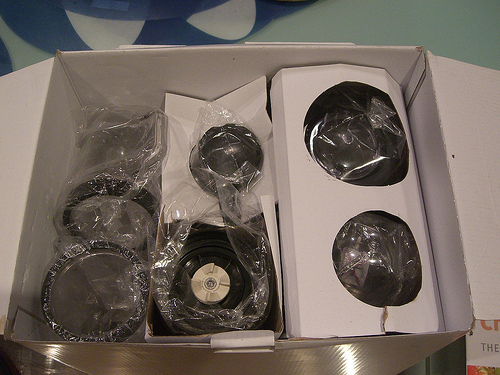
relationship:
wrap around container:
[68, 105, 165, 246] [64, 182, 162, 251]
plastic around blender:
[158, 186, 272, 337] [166, 240, 269, 318]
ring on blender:
[170, 241, 252, 313] [166, 240, 269, 318]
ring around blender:
[170, 241, 252, 313] [166, 240, 269, 318]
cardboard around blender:
[163, 74, 277, 226] [166, 240, 269, 318]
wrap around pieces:
[68, 105, 165, 246] [43, 125, 272, 341]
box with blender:
[1, 44, 499, 372] [166, 240, 269, 318]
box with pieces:
[1, 44, 499, 372] [43, 125, 272, 341]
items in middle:
[185, 115, 272, 203] [164, 46, 291, 343]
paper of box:
[262, 196, 284, 339] [1, 44, 499, 372]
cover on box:
[272, 63, 448, 339] [1, 44, 499, 372]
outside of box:
[2, 336, 445, 374] [1, 44, 499, 372]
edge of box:
[246, 41, 425, 56] [1, 44, 499, 372]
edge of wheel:
[79, 240, 125, 249] [41, 236, 148, 341]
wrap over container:
[68, 105, 165, 246] [52, 170, 170, 251]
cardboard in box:
[163, 74, 277, 226] [1, 44, 499, 372]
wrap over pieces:
[68, 105, 165, 246] [43, 125, 272, 341]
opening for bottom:
[329, 211, 426, 309] [327, 208, 431, 315]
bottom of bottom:
[370, 269, 398, 297] [327, 208, 431, 315]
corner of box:
[402, 46, 424, 97] [1, 44, 499, 372]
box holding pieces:
[1, 44, 499, 372] [43, 125, 272, 341]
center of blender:
[205, 280, 218, 291] [141, 221, 282, 344]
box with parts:
[1, 44, 499, 372] [41, 95, 416, 338]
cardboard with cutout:
[163, 74, 277, 226] [187, 124, 264, 192]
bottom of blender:
[370, 269, 398, 297] [166, 240, 269, 318]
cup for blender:
[43, 240, 148, 343] [166, 240, 269, 318]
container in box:
[52, 170, 170, 251] [1, 44, 499, 372]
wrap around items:
[68, 105, 165, 246] [162, 124, 271, 330]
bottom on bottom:
[187, 260, 235, 307] [159, 243, 258, 323]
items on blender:
[185, 115, 272, 203] [166, 240, 269, 318]